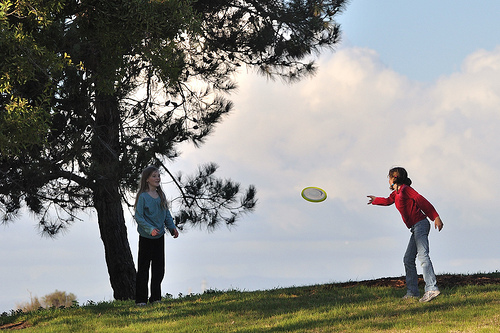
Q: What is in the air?
A: Frisbee.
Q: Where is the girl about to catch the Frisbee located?
A: Under a tree.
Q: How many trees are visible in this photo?
A: One.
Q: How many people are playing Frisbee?
A: Two.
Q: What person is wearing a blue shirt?
A: The person under the tree.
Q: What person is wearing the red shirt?
A: The person not under the tree.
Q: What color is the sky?
A: Blue.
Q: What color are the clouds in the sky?
A: White.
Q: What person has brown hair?
A: The person in the red shirt.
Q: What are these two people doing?
A: Playing Frisbee.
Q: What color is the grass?
A: Green.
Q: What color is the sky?
A: Blue.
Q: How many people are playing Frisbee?
A: Two.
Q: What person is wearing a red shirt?
A: The person not under the free.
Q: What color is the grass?
A: Green.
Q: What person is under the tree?
A: The person wearing the blue shirt.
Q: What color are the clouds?
A: White.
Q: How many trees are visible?
A: One.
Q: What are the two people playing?
A: Frisbee.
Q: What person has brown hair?
A: The person not under the tree.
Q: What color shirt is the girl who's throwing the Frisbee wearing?
A: Red.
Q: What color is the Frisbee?
A: White.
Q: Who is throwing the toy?
A: Girl in red.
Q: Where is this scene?
A: Outside by a tree.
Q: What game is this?
A: Frisbee.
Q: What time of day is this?
A: Day time.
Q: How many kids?
A: 2.